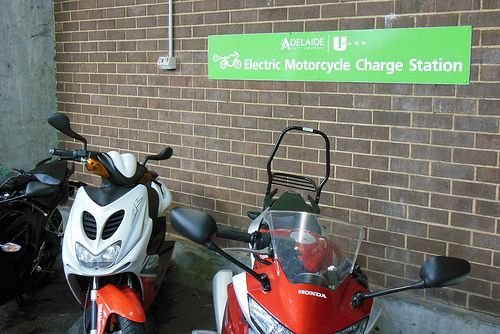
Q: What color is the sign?
A: Green.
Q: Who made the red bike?
A: Honda.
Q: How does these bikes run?
A: Off of electric.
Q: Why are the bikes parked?
A: To use charging station.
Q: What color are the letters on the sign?
A: White.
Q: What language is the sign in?
A: English.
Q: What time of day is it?
A: Daytime.